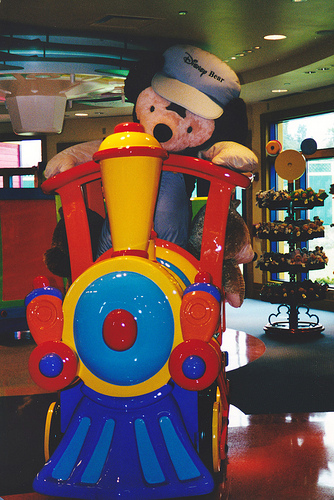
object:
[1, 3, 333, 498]
scene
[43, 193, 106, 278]
toy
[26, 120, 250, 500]
toy train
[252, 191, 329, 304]
rack of toys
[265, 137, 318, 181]
mickey mouse head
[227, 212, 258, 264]
bear head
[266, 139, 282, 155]
ears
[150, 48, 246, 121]
hat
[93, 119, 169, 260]
smoke stack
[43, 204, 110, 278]
teddy bear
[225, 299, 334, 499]
floor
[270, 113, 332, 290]
window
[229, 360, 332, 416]
rug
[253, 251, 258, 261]
nose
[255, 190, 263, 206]
stuffed animals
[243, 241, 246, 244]
eye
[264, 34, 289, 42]
light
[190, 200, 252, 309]
bear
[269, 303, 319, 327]
design on base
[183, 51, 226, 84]
disney bear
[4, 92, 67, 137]
center chandalier